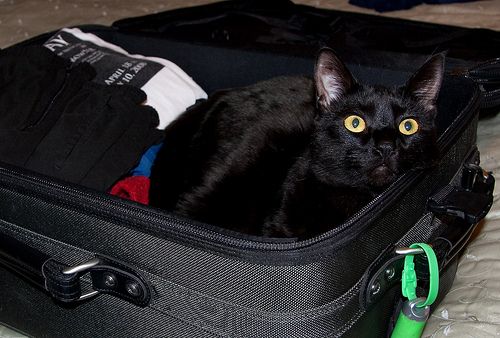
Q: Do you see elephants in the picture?
A: No, there are no elephants.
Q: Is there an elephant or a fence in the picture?
A: No, there are no elephants or fences.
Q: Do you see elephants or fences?
A: No, there are no elephants or fences.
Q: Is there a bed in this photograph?
A: Yes, there is a bed.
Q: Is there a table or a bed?
A: Yes, there is a bed.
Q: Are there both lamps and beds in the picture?
A: No, there is a bed but no lamps.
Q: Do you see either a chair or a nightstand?
A: No, there are no chairs or nightstands.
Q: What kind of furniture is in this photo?
A: The furniture is a bed.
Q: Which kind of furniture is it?
A: The piece of furniture is a bed.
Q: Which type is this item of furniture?
A: This is a bed.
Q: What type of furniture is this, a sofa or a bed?
A: This is a bed.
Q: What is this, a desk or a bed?
A: This is a bed.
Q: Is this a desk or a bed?
A: This is a bed.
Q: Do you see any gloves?
A: Yes, there are gloves.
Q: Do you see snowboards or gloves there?
A: Yes, there are gloves.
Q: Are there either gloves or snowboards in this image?
A: Yes, there are gloves.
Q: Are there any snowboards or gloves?
A: Yes, there are gloves.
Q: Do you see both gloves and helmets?
A: No, there are gloves but no helmets.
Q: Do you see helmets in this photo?
A: No, there are no helmets.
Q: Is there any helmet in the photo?
A: No, there are no helmets.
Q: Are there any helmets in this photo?
A: No, there are no helmets.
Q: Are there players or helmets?
A: No, there are no helmets or players.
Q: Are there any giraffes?
A: No, there are no giraffes.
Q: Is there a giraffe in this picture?
A: No, there are no giraffes.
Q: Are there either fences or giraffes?
A: No, there are no giraffes or fences.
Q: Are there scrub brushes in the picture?
A: No, there are no scrub brushes.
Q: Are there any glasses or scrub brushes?
A: No, there are no scrub brushes or glasses.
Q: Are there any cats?
A: Yes, there is a cat.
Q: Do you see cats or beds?
A: Yes, there is a cat.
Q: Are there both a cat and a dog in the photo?
A: No, there is a cat but no dogs.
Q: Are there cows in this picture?
A: No, there are no cows.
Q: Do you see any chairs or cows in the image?
A: No, there are no cows or chairs.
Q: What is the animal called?
A: The animal is a cat.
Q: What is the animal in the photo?
A: The animal is a cat.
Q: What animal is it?
A: The animal is a cat.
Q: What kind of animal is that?
A: That is a cat.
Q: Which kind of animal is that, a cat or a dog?
A: That is a cat.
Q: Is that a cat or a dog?
A: That is a cat.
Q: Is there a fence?
A: No, there are no fences.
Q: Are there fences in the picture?
A: No, there are no fences.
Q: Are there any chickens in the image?
A: No, there are no chickens.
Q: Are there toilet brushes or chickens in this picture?
A: No, there are no chickens or toilet brushes.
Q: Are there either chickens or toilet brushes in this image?
A: No, there are no chickens or toilet brushes.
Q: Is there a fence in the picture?
A: No, there are no fences.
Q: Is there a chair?
A: No, there are no chairs.